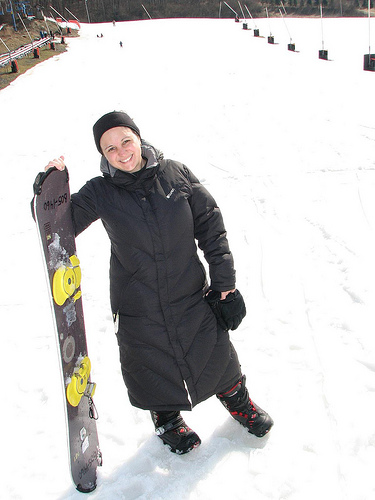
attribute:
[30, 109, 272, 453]
person — black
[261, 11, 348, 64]
poles — white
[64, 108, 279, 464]
woman — standing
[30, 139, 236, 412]
coat — black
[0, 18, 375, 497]
snow — white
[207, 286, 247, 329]
gloves — black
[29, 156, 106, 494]
snowboard — black, yellow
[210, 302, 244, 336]
gloves — black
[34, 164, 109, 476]
snowboard — gray, yellow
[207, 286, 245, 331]
glove — black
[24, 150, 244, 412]
jacket — long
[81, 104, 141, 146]
cap — black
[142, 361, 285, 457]
boot — black, red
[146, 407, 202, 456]
boot — black, red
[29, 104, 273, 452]
woman — long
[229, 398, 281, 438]
boots — black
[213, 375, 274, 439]
boot — black, red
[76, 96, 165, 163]
hat — woman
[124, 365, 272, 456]
boots — black, red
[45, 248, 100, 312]
foothold — yellow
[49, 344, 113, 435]
foothold — yellow